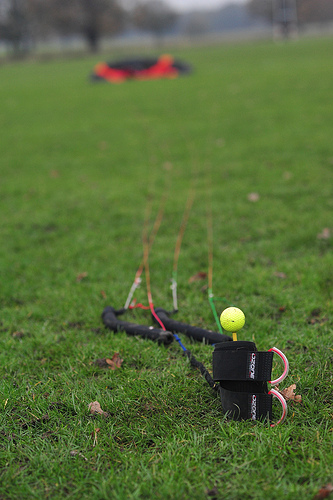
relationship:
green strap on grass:
[207, 288, 222, 337] [2, 36, 333, 493]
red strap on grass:
[139, 247, 167, 336] [15, 87, 268, 252]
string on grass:
[206, 194, 214, 288] [8, 89, 307, 279]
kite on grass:
[86, 52, 196, 86] [35, 96, 268, 229]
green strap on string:
[208, 289, 223, 333] [197, 191, 215, 284]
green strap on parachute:
[208, 289, 223, 333] [72, 34, 202, 90]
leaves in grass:
[61, 351, 144, 444] [8, 122, 317, 491]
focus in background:
[5, 6, 322, 164] [11, 5, 310, 282]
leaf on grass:
[273, 383, 301, 405] [12, 49, 314, 489]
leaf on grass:
[280, 382, 304, 406] [12, 49, 314, 489]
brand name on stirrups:
[247, 348, 262, 376] [203, 342, 278, 417]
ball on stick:
[219, 305, 246, 332] [231, 330, 237, 340]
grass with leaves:
[2, 39, 328, 493] [87, 401, 109, 419]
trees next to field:
[2, 2, 179, 53] [4, 37, 331, 498]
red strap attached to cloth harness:
[144, 259, 166, 331] [219, 387, 273, 423]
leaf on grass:
[185, 264, 217, 287] [12, 49, 314, 489]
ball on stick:
[219, 305, 246, 332] [232, 332, 237, 341]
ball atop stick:
[218, 302, 248, 331] [226, 328, 239, 340]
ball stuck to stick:
[218, 302, 248, 331] [227, 332, 239, 340]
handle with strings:
[97, 299, 166, 344] [134, 222, 238, 325]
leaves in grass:
[87, 401, 109, 419] [2, 39, 328, 493]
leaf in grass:
[273, 383, 301, 405] [12, 49, 314, 489]